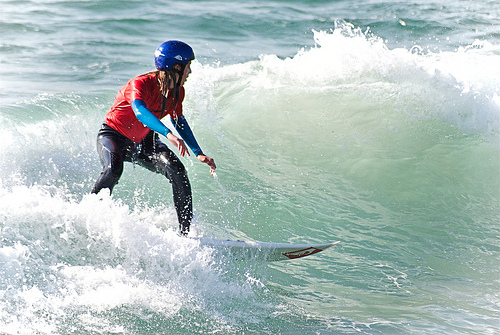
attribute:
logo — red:
[283, 245, 322, 259]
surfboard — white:
[197, 234, 339, 262]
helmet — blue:
[156, 40, 196, 70]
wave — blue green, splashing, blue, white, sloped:
[1, 19, 498, 332]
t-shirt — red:
[108, 67, 185, 140]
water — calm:
[0, 1, 492, 106]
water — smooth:
[3, 87, 251, 216]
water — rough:
[4, 178, 228, 327]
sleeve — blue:
[133, 102, 173, 144]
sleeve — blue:
[172, 105, 202, 159]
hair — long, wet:
[156, 60, 179, 101]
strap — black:
[163, 64, 187, 88]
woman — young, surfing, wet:
[87, 39, 217, 239]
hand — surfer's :
[197, 151, 219, 176]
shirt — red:
[83, 60, 228, 155]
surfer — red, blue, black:
[92, 41, 218, 239]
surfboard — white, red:
[224, 225, 338, 262]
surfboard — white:
[192, 228, 349, 267]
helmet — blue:
[150, 35, 195, 75]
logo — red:
[279, 246, 322, 260]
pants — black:
[91, 126, 192, 232]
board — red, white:
[187, 233, 338, 264]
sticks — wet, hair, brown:
[160, 65, 187, 107]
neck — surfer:
[152, 66, 189, 102]